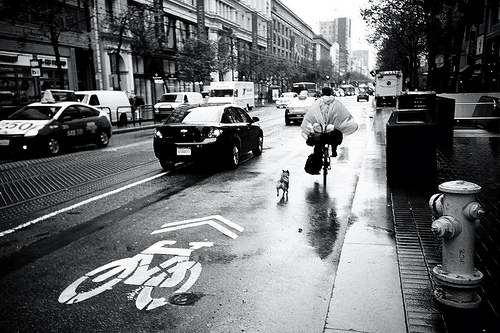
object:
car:
[153, 102, 264, 172]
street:
[0, 94, 374, 329]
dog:
[274, 167, 291, 201]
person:
[300, 86, 359, 159]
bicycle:
[318, 134, 332, 184]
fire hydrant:
[426, 179, 487, 310]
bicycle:
[56, 238, 216, 313]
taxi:
[0, 88, 113, 158]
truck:
[207, 80, 255, 113]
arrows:
[150, 220, 239, 240]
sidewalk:
[391, 124, 499, 332]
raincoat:
[300, 95, 359, 139]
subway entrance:
[434, 92, 500, 145]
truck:
[371, 69, 403, 108]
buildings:
[0, 0, 100, 113]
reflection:
[302, 179, 341, 261]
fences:
[116, 105, 136, 128]